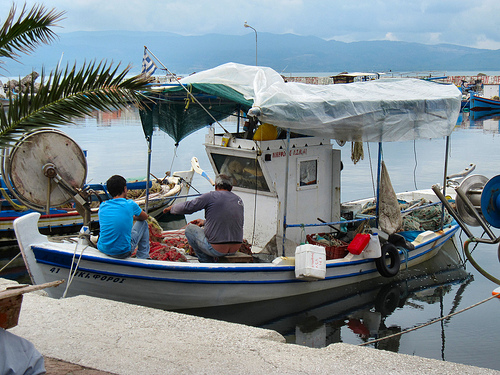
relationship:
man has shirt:
[163, 173, 245, 263] [188, 191, 240, 243]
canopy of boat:
[121, 57, 461, 156] [18, 200, 458, 313]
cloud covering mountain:
[435, 14, 490, 46] [0, 26, 500, 76]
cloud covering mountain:
[421, 0, 488, 12] [0, 26, 500, 76]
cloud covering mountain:
[291, 2, 388, 37] [0, 26, 500, 76]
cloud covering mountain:
[150, 1, 260, 33] [0, 26, 500, 76]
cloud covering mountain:
[30, 0, 127, 31] [0, 26, 500, 76]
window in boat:
[276, 147, 348, 215] [61, 102, 436, 354]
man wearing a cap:
[197, 172, 235, 251] [215, 172, 228, 186]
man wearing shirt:
[94, 174, 151, 266] [100, 196, 137, 255]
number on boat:
[45, 265, 58, 275] [24, 59, 467, 307]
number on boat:
[55, 262, 64, 280] [14, 50, 442, 372]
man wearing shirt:
[163, 173, 245, 263] [99, 190, 153, 265]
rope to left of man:
[57, 253, 91, 300] [96, 174, 150, 260]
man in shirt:
[96, 174, 150, 260] [96, 198, 138, 255]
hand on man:
[186, 215, 208, 230] [163, 173, 245, 263]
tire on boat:
[376, 242, 401, 277] [10, 177, 468, 347]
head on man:
[213, 173, 235, 191] [163, 173, 245, 263]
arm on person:
[131, 202, 146, 221] [94, 174, 149, 259]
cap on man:
[213, 173, 234, 186] [95, 176, 157, 276]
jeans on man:
[185, 217, 239, 262] [158, 170, 245, 266]